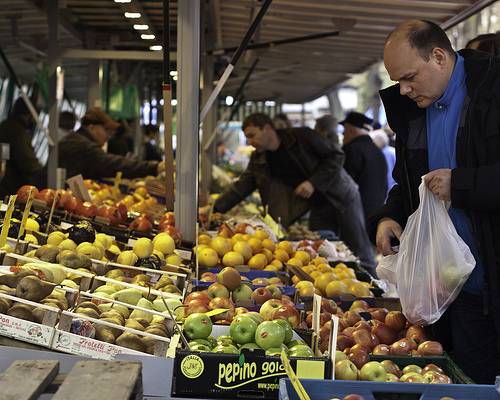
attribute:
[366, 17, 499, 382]
man — black, gray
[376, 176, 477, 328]
bag — plastic, transparent white, white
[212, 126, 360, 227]
jacket — brown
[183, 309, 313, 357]
apples — green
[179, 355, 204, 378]
circle — yellow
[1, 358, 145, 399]
pallet — wooden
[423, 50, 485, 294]
shirt — blue, bright blue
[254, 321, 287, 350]
apple — green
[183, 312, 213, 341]
apple — green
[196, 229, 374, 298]
oranges — vibrant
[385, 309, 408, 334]
apple — red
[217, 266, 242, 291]
apple — green, red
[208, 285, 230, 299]
apple — green, red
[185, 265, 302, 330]
apples — green, red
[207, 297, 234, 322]
apple — green, red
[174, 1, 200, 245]
pole — gray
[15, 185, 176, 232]
peppers — bright red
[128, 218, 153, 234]
pepper — bright red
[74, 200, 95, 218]
pepper — bright red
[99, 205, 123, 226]
pepper — bright red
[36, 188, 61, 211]
pepper — bright red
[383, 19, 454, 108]
head — bald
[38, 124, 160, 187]
jacket — brown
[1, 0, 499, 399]
metal building — farmers market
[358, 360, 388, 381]
fruit — red, green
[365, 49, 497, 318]
coat — black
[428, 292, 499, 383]
pants — dark